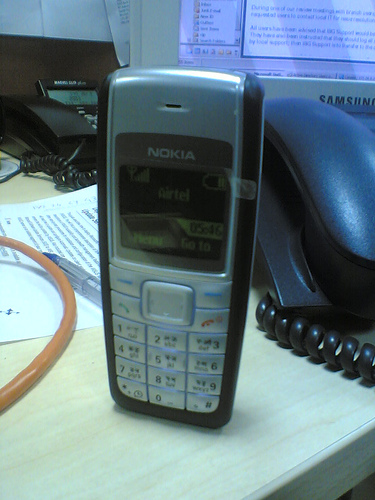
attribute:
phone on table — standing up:
[88, 61, 270, 433]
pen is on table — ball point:
[37, 245, 109, 315]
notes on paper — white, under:
[12, 209, 114, 288]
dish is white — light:
[1, 145, 22, 185]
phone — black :
[82, 59, 279, 461]